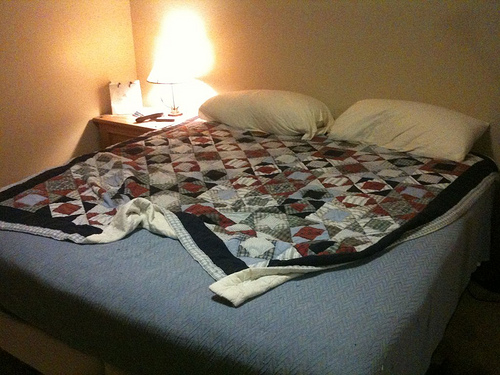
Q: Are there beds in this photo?
A: Yes, there is a bed.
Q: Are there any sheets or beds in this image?
A: Yes, there is a bed.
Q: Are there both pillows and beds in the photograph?
A: Yes, there are both a bed and a pillow.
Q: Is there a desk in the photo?
A: No, there are no desks.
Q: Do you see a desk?
A: No, there are no desks.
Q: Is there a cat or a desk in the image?
A: No, there are no desks or cats.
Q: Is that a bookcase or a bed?
A: That is a bed.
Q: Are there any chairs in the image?
A: No, there are no chairs.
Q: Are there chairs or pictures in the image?
A: No, there are no chairs or pictures.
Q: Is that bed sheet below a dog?
A: No, the bed sheet is below the bed cover.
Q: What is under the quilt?
A: The bed sheet is under the quilt.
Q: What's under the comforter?
A: The bed sheet is under the quilt.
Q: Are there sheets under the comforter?
A: Yes, there is a sheet under the comforter.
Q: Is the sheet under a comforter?
A: Yes, the sheet is under a comforter.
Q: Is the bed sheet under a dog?
A: No, the bed sheet is under a comforter.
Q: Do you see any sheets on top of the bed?
A: Yes, there is a sheet on top of the bed.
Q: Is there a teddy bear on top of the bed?
A: No, there is a sheet on top of the bed.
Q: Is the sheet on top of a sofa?
A: No, the sheet is on top of the bed.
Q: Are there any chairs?
A: No, there are no chairs.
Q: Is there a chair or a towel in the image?
A: No, there are no chairs or towels.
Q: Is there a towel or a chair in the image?
A: No, there are no chairs or towels.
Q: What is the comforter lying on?
A: The comforter is lying on the bed.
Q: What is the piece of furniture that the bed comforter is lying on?
A: The piece of furniture is a bed.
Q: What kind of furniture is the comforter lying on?
A: The bed cover is lying on the bed.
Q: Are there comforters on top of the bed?
A: Yes, there is a comforter on top of the bed.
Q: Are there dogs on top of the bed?
A: No, there is a comforter on top of the bed.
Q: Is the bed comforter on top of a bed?
A: Yes, the quilt is on top of a bed.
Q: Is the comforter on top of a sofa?
A: No, the comforter is on top of a bed.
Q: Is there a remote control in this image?
A: Yes, there is a remote control.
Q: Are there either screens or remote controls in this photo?
A: Yes, there is a remote control.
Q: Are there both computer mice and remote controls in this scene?
A: No, there is a remote control but no computer mice.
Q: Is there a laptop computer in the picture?
A: No, there are no laptops.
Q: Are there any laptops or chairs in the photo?
A: No, there are no laptops or chairs.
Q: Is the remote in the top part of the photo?
A: Yes, the remote is in the top of the image.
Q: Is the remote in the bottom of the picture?
A: No, the remote is in the top of the image.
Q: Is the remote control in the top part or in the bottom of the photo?
A: The remote control is in the top of the image.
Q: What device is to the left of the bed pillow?
A: The device is a remote control.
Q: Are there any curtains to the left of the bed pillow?
A: No, there is a remote control to the left of the pillow.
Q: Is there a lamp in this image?
A: Yes, there is a lamp.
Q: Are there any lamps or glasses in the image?
A: Yes, there is a lamp.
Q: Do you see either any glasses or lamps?
A: Yes, there is a lamp.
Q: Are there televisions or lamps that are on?
A: Yes, the lamp is on.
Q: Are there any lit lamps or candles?
A: Yes, there is a lit lamp.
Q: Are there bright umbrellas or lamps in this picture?
A: Yes, there is a bright lamp.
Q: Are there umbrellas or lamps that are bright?
A: Yes, the lamp is bright.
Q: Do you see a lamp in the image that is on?
A: Yes, there is a lamp that is on.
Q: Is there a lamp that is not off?
A: Yes, there is a lamp that is on.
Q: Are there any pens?
A: No, there are no pens.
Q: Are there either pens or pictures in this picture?
A: No, there are no pens or pictures.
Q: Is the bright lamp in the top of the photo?
A: Yes, the lamp is in the top of the image.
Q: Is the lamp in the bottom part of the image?
A: No, the lamp is in the top of the image.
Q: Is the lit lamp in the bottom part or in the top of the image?
A: The lamp is in the top of the image.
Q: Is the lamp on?
A: Yes, the lamp is on.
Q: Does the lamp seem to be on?
A: Yes, the lamp is on.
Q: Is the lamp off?
A: No, the lamp is on.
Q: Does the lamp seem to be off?
A: No, the lamp is on.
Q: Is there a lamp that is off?
A: No, there is a lamp but it is on.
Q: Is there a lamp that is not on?
A: No, there is a lamp but it is on.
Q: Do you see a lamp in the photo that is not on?
A: No, there is a lamp but it is on.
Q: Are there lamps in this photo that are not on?
A: No, there is a lamp but it is on.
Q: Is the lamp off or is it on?
A: The lamp is on.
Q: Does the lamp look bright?
A: Yes, the lamp is bright.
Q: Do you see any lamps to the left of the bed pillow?
A: Yes, there is a lamp to the left of the pillow.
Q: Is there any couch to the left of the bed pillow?
A: No, there is a lamp to the left of the pillow.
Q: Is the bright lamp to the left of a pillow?
A: Yes, the lamp is to the left of a pillow.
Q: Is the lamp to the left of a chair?
A: No, the lamp is to the left of a pillow.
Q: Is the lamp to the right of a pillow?
A: No, the lamp is to the left of a pillow.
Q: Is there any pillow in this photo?
A: Yes, there is a pillow.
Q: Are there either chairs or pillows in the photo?
A: Yes, there is a pillow.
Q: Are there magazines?
A: No, there are no magazines.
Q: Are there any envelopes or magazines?
A: No, there are no magazines or envelopes.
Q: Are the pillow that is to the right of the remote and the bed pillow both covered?
A: Yes, both the pillow and the pillow are covered.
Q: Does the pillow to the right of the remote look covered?
A: Yes, the pillow is covered.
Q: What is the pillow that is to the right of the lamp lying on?
A: The pillow is lying on the bed.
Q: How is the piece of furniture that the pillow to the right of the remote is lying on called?
A: The piece of furniture is a bed.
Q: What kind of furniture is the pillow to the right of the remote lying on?
A: The pillow is lying on the bed.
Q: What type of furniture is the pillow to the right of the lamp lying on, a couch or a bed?
A: The pillow is lying on a bed.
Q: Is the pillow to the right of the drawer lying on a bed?
A: Yes, the pillow is lying on a bed.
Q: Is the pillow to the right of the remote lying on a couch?
A: No, the pillow is lying on a bed.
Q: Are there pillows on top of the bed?
A: Yes, there is a pillow on top of the bed.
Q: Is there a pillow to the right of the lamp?
A: Yes, there is a pillow to the right of the lamp.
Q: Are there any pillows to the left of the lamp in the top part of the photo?
A: No, the pillow is to the right of the lamp.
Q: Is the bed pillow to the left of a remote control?
A: No, the pillow is to the right of a remote control.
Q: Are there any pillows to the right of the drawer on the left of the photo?
A: Yes, there is a pillow to the right of the drawer.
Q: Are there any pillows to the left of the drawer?
A: No, the pillow is to the right of the drawer.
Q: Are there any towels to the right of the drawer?
A: No, there is a pillow to the right of the drawer.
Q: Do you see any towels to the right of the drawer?
A: No, there is a pillow to the right of the drawer.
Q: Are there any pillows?
A: Yes, there is a pillow.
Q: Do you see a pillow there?
A: Yes, there is a pillow.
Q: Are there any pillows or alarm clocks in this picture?
A: Yes, there is a pillow.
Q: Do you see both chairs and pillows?
A: No, there is a pillow but no chairs.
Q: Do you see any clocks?
A: No, there are no clocks.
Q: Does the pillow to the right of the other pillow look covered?
A: Yes, the pillow is covered.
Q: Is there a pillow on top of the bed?
A: Yes, there is a pillow on top of the bed.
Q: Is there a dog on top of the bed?
A: No, there is a pillow on top of the bed.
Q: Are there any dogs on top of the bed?
A: No, there is a pillow on top of the bed.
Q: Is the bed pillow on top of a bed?
A: Yes, the pillow is on top of a bed.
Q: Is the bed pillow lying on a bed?
A: Yes, the pillow is lying on a bed.